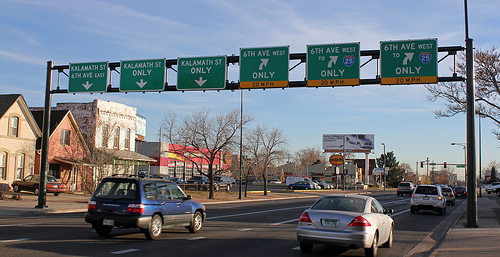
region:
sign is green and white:
[69, 63, 108, 90]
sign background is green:
[119, 60, 164, 90]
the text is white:
[182, 58, 222, 87]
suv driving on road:
[85, 172, 205, 234]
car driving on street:
[296, 195, 393, 252]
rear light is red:
[350, 216, 372, 226]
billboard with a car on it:
[322, 133, 372, 150]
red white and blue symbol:
[418, 50, 428, 63]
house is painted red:
[38, 115, 85, 190]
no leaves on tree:
[160, 111, 249, 196]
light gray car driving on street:
[292, 190, 397, 255]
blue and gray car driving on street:
[82, 171, 211, 241]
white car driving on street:
[406, 178, 448, 219]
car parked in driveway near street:
[8, 168, 70, 199]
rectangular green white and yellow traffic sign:
[378, 34, 440, 87]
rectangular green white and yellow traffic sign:
[303, 38, 363, 88]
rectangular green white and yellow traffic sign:
[236, 43, 291, 89]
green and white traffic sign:
[173, 49, 230, 94]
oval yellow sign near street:
[326, 151, 348, 166]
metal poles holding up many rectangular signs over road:
[31, 33, 481, 231]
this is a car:
[290, 182, 402, 254]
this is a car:
[81, 155, 209, 237]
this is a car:
[390, 163, 446, 218]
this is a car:
[378, 163, 414, 203]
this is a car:
[429, 174, 456, 203]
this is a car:
[286, 168, 311, 197]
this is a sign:
[64, 58, 106, 96]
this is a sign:
[116, 54, 168, 92]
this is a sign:
[174, 52, 230, 98]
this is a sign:
[237, 43, 288, 93]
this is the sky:
[161, 12, 241, 45]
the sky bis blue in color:
[224, 17, 284, 53]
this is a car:
[313, 176, 392, 239]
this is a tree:
[190, 115, 237, 145]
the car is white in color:
[408, 192, 425, 199]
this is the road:
[228, 195, 270, 241]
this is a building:
[83, 105, 150, 162]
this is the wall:
[111, 104, 138, 121]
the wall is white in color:
[112, 103, 139, 118]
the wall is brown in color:
[18, 123, 40, 159]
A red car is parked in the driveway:
[1, 85, 65, 212]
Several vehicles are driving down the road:
[77, 143, 466, 248]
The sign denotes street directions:
[28, 32, 453, 101]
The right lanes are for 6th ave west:
[234, 34, 457, 99]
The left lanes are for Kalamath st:
[55, 46, 230, 98]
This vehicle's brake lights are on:
[400, 179, 449, 216]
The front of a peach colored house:
[36, 106, 93, 195]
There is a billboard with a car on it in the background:
[320, 128, 375, 160]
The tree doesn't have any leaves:
[160, 108, 250, 204]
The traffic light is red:
[410, 157, 466, 178]